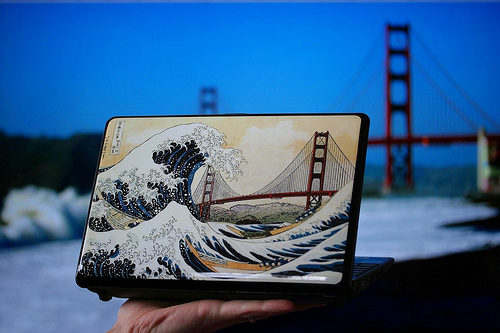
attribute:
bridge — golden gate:
[379, 18, 496, 192]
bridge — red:
[204, 41, 451, 253]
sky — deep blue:
[183, 25, 258, 60]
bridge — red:
[340, 17, 497, 180]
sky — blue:
[126, 2, 493, 167]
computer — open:
[71, 110, 371, 302]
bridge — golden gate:
[192, 146, 344, 210]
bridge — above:
[254, 54, 455, 186]